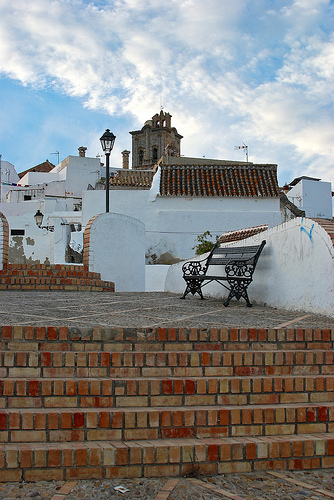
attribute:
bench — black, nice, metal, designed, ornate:
[151, 225, 307, 315]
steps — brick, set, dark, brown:
[1, 318, 332, 474]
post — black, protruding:
[72, 107, 119, 208]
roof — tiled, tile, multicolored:
[137, 144, 296, 208]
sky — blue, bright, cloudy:
[12, 17, 312, 141]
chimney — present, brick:
[106, 101, 182, 160]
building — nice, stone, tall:
[37, 137, 294, 249]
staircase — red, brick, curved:
[6, 185, 302, 475]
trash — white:
[83, 471, 156, 499]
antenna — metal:
[193, 129, 288, 183]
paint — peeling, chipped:
[112, 213, 239, 253]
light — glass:
[99, 134, 122, 156]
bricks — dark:
[43, 365, 220, 435]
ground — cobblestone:
[26, 474, 204, 499]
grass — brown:
[175, 457, 208, 480]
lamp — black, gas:
[94, 130, 156, 209]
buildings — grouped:
[39, 145, 333, 293]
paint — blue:
[265, 220, 313, 263]